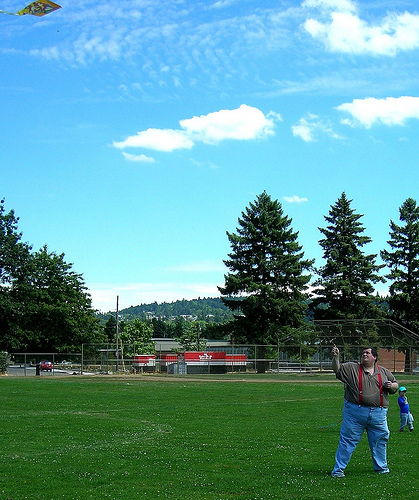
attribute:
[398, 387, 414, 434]
boy — standing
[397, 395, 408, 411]
shirt — green, blue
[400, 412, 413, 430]
pants — blue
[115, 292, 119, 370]
telephone pole — tall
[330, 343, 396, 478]
guy — big, standing, pointing up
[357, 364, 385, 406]
suspenders — red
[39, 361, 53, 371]
car — red, driving, small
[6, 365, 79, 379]
parking lot — gray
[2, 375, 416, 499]
field — grass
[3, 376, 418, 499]
grass — green, dark green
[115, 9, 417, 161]
clouds — white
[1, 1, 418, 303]
sky — blue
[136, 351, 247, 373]
buildings — red, white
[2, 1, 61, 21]
kite — colorful, yellow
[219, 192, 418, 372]
trees — growing, evergreen, green, three, tall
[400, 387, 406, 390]
hat — green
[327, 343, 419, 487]
man and child — standing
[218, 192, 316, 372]
tree — big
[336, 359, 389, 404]
shirt — blue, brown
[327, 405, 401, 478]
jeans — blue